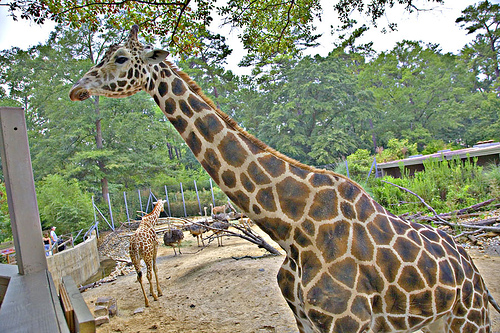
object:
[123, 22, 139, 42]
horns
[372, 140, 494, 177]
structure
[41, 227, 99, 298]
brick wall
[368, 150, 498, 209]
branchges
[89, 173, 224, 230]
metal poles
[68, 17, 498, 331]
giraffe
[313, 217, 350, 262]
spot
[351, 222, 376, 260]
spot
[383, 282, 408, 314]
spot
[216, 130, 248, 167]
spot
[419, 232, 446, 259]
spot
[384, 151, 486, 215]
weeds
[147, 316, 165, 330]
rock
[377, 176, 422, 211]
bush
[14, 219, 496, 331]
dirt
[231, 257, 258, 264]
root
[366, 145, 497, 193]
house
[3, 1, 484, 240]
background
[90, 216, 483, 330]
ground